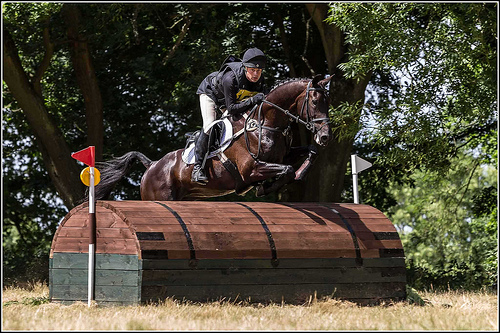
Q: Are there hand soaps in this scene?
A: No, there are no hand soaps.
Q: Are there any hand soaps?
A: No, there are no hand soaps.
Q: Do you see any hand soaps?
A: No, there are no hand soaps.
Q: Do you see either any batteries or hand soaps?
A: No, there are no hand soaps or batteries.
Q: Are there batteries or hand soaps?
A: No, there are no hand soaps or batteries.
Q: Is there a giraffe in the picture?
A: No, there are no giraffes.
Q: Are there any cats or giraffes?
A: No, there are no giraffes or cats.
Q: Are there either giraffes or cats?
A: No, there are no giraffes or cats.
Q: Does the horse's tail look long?
A: Yes, the tail is long.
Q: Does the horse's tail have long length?
A: Yes, the tail is long.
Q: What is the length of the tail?
A: The tail is long.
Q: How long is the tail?
A: The tail is long.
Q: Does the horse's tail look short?
A: No, the tail is long.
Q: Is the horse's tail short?
A: No, the tail is long.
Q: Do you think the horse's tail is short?
A: No, the tail is long.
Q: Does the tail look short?
A: No, the tail is long.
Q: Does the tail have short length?
A: No, the tail is long.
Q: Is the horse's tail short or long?
A: The tail is long.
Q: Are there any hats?
A: Yes, there is a hat.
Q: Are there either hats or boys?
A: Yes, there is a hat.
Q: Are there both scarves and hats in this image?
A: No, there is a hat but no scarves.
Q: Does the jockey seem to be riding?
A: Yes, the jockey is riding.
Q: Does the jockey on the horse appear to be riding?
A: Yes, the jockey is riding.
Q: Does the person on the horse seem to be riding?
A: Yes, the jockey is riding.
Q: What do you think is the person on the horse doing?
A: The jockey is riding.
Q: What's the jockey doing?
A: The jockey is riding.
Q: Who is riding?
A: The jockey is riding.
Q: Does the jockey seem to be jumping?
A: Yes, the jockey is jumping.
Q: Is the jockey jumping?
A: Yes, the jockey is jumping.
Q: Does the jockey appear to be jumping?
A: Yes, the jockey is jumping.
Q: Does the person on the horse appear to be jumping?
A: Yes, the jockey is jumping.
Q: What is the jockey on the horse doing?
A: The jockey is jumping.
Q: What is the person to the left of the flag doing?
A: The jockey is jumping.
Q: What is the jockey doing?
A: The jockey is jumping.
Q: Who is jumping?
A: The jockey is jumping.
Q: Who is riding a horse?
A: The jockey is riding a horse.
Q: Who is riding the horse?
A: The jockey is riding a horse.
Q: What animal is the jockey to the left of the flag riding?
A: The jockey is riding a horse.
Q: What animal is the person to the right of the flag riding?
A: The jockey is riding a horse.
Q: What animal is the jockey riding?
A: The jockey is riding a horse.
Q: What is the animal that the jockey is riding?
A: The animal is a horse.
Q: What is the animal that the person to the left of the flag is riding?
A: The animal is a horse.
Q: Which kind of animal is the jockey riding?
A: The jockey is riding a horse.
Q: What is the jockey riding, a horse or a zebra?
A: The jockey is riding a horse.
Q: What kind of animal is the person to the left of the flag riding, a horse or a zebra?
A: The jockey is riding a horse.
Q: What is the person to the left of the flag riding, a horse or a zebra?
A: The jockey is riding a horse.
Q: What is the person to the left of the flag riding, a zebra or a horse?
A: The jockey is riding a horse.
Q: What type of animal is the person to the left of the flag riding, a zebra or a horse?
A: The jockey is riding a horse.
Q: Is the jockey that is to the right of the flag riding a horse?
A: Yes, the jockey is riding a horse.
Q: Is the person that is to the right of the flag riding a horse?
A: Yes, the jockey is riding a horse.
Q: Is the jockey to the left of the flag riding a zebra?
A: No, the jockey is riding a horse.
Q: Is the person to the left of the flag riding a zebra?
A: No, the jockey is riding a horse.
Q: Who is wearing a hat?
A: The jockey is wearing a hat.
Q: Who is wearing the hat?
A: The jockey is wearing a hat.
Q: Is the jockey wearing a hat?
A: Yes, the jockey is wearing a hat.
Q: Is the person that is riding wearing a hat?
A: Yes, the jockey is wearing a hat.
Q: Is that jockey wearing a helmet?
A: No, the jockey is wearing a hat.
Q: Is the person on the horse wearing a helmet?
A: No, the jockey is wearing a hat.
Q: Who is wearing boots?
A: The jockey is wearing boots.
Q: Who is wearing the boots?
A: The jockey is wearing boots.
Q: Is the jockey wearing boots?
A: Yes, the jockey is wearing boots.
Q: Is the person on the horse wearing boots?
A: Yes, the jockey is wearing boots.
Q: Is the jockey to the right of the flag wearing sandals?
A: No, the jockey is wearing boots.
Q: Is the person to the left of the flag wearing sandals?
A: No, the jockey is wearing boots.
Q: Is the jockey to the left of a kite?
A: No, the jockey is to the left of the flag.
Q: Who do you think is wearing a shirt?
A: The jockey is wearing a shirt.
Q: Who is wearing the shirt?
A: The jockey is wearing a shirt.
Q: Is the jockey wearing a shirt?
A: Yes, the jockey is wearing a shirt.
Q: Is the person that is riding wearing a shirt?
A: Yes, the jockey is wearing a shirt.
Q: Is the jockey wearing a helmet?
A: No, the jockey is wearing a shirt.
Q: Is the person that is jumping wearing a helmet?
A: No, the jockey is wearing a shirt.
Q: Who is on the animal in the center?
A: The jockey is on the horse.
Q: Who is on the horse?
A: The jockey is on the horse.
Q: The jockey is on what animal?
A: The jockey is on the horse.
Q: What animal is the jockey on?
A: The jockey is on the horse.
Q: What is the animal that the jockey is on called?
A: The animal is a horse.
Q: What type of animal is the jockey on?
A: The jockey is on the horse.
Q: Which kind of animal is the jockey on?
A: The jockey is on the horse.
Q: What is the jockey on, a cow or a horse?
A: The jockey is on a horse.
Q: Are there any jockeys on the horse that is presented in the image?
A: Yes, there is a jockey on the horse.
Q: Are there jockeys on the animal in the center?
A: Yes, there is a jockey on the horse.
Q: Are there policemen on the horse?
A: No, there is a jockey on the horse.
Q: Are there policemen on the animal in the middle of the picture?
A: No, there is a jockey on the horse.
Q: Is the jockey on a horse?
A: Yes, the jockey is on a horse.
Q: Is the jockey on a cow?
A: No, the jockey is on a horse.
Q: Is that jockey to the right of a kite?
A: No, the jockey is to the right of the flag.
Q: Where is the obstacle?
A: The obstacle is on the grass.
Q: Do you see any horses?
A: Yes, there is a horse.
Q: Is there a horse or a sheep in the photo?
A: Yes, there is a horse.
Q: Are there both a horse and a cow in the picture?
A: No, there is a horse but no cows.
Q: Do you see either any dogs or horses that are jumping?
A: Yes, the horse is jumping.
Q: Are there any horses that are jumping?
A: Yes, there is a horse that is jumping.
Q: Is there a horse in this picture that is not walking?
A: Yes, there is a horse that is jumping.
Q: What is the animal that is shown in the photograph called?
A: The animal is a horse.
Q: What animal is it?
A: The animal is a horse.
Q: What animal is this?
A: This is a horse.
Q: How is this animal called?
A: This is a horse.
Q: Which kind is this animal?
A: This is a horse.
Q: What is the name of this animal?
A: This is a horse.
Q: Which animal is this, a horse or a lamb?
A: This is a horse.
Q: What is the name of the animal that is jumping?
A: The animal is a horse.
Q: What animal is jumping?
A: The animal is a horse.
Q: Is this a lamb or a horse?
A: This is a horse.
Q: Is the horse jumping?
A: Yes, the horse is jumping.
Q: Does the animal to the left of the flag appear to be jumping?
A: Yes, the horse is jumping.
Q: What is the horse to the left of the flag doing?
A: The horse is jumping.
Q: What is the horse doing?
A: The horse is jumping.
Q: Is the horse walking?
A: No, the horse is jumping.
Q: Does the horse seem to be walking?
A: No, the horse is jumping.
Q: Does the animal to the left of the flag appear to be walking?
A: No, the horse is jumping.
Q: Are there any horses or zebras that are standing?
A: No, there is a horse but it is jumping.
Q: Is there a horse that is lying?
A: No, there is a horse but it is jumping.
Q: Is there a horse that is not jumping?
A: No, there is a horse but it is jumping.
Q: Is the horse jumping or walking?
A: The horse is jumping.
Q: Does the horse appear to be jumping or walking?
A: The horse is jumping.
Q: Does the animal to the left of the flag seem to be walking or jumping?
A: The horse is jumping.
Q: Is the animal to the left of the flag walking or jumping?
A: The horse is jumping.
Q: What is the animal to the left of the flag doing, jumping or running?
A: The horse is jumping.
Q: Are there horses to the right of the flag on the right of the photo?
A: No, the horse is to the left of the flag.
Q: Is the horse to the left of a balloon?
A: No, the horse is to the left of a flag.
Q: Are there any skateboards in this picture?
A: No, there are no skateboards.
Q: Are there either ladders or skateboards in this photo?
A: No, there are no skateboards or ladders.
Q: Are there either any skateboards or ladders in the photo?
A: No, there are no skateboards or ladders.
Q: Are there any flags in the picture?
A: Yes, there is a flag.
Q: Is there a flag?
A: Yes, there is a flag.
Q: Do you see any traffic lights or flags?
A: Yes, there is a flag.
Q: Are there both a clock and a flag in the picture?
A: No, there is a flag but no clocks.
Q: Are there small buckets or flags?
A: Yes, there is a small flag.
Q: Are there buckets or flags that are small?
A: Yes, the flag is small.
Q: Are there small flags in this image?
A: Yes, there is a small flag.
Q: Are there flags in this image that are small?
A: Yes, there is a flag that is small.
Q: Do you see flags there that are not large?
A: Yes, there is a small flag.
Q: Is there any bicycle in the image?
A: No, there are no bicycles.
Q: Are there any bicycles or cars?
A: No, there are no bicycles or cars.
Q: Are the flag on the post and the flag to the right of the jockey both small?
A: Yes, both the flag and the flag are small.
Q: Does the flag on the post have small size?
A: Yes, the flag is small.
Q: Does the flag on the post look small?
A: Yes, the flag is small.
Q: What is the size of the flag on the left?
A: The flag is small.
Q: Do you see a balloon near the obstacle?
A: No, there is a flag near the obstacle.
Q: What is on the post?
A: The flag is on the post.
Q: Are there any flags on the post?
A: Yes, there is a flag on the post.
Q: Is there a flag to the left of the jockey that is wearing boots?
A: Yes, there is a flag to the left of the jockey.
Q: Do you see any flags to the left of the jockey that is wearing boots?
A: Yes, there is a flag to the left of the jockey.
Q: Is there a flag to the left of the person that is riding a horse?
A: Yes, there is a flag to the left of the jockey.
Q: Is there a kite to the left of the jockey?
A: No, there is a flag to the left of the jockey.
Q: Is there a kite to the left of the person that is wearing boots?
A: No, there is a flag to the left of the jockey.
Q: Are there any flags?
A: Yes, there is a flag.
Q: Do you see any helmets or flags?
A: Yes, there is a flag.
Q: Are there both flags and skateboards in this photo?
A: No, there is a flag but no skateboards.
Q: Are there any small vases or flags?
A: Yes, there is a small flag.